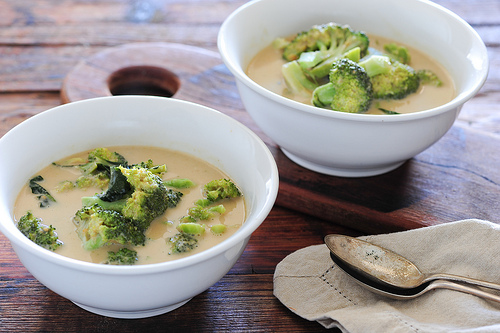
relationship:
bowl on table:
[215, 0, 492, 180] [0, 2, 498, 332]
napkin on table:
[271, 219, 497, 332] [0, 2, 498, 332]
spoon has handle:
[323, 233, 500, 291] [428, 270, 498, 290]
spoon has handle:
[323, 233, 500, 291] [430, 278, 499, 306]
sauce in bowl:
[10, 139, 252, 269] [8, 87, 275, 319]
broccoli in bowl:
[14, 209, 65, 252] [8, 87, 275, 319]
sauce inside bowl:
[10, 141, 246, 265] [8, 87, 275, 319]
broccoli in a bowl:
[65, 147, 163, 208] [203, 34, 447, 188]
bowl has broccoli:
[203, 34, 447, 188] [65, 147, 163, 208]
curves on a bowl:
[211, 0, 496, 179] [213, 0, 490, 178]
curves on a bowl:
[0, 95, 281, 277] [213, 0, 490, 178]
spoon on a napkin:
[323, 226, 497, 316] [267, 199, 496, 326]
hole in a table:
[104, 63, 182, 98] [2, 3, 57, 98]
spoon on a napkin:
[323, 233, 500, 291] [266, 211, 497, 329]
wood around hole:
[323, 138, 491, 218] [102, 59, 184, 105]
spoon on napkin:
[323, 233, 500, 291] [271, 218, 500, 333]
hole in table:
[105, 63, 180, 100] [32, 10, 119, 87]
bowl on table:
[8, 87, 275, 319] [267, 217, 302, 261]